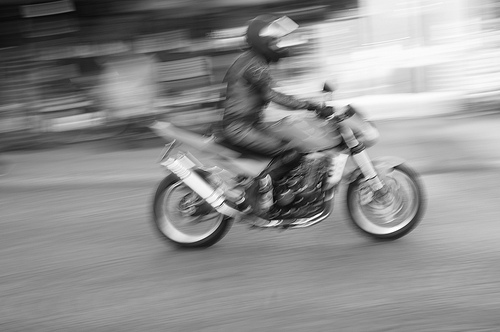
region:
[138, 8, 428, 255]
A motorcylists riding fast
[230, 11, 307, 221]
A blurry motorcyclist wearing a helmet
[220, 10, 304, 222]
A motorcyclist driving a motorcycle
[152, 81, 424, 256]
A black and white motorcycle speeding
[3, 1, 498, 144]
Blurry black and white stores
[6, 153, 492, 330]
A blurry gray road with a curb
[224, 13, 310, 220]
A motorcyclist driving very fast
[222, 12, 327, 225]
Motorcyclist wearing all dark outfit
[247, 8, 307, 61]
Motorcycle helmet with white visor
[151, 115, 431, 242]
A light colored motorcycle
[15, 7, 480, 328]
Photo is in black and white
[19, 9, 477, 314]
Photo is out of focus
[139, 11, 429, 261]
The person is on a motorbike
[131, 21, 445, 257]
The motorbike is moving forward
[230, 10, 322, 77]
The person is wearing a helmet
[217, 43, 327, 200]
The person is wearing a leather outfit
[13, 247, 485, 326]
The ground is made of dirt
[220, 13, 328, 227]
The right side of the person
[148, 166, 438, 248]
The wheels are round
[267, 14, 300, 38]
The helmet has a visor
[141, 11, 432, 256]
A motorcyclists riding fast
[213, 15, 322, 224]
a person sitting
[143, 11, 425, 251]
a person sitting on a motorcycle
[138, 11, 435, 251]
someone riding on a motorcycle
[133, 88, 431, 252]
a motorcycle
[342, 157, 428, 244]
the front wheel of a motorcycle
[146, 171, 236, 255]
the back wheel of a motorcycle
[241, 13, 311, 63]
a person wearing a motorcycle helmet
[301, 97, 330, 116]
a black glove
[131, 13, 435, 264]
a person driving a motorcycle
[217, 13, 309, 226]
a person dressed in black